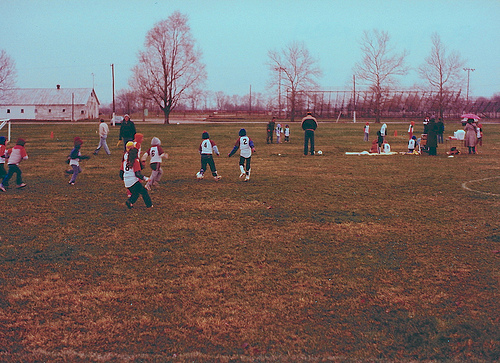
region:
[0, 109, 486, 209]
Children playing soccer on a field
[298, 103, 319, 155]
Man standing on a soccer field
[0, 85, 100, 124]
Large old white barn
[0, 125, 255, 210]
Children running after a soccer ball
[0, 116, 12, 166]
White frame soccer net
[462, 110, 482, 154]
Woman in a dress jacket and umbrella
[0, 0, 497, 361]
People on a soccer field on a cold day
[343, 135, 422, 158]
Children sitting on a blanket on the ground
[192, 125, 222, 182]
Small child kicking a soccer ball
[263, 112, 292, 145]
Man and two children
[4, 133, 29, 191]
child playing in field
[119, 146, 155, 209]
child playing in field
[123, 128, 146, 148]
child playing in field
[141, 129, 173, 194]
child playing in field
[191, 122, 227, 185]
child playing in field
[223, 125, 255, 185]
child playing in field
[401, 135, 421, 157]
child playing in field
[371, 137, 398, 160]
child playing in field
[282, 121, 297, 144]
child playing in field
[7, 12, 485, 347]
playing field with a game in progress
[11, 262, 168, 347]
brown grass on the field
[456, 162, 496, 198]
circular line drawn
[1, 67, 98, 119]
long building in the background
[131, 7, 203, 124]
bare tree on the side of the road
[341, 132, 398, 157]
people sitting on a white blanket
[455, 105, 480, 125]
two umbrellas opened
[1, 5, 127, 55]
clear and blue sky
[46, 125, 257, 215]
player's from both teams pursue the ball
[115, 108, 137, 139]
adult watching the action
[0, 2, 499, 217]
Children playing soccer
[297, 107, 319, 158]
The man is standing with his back to the camera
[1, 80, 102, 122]
A building behind the soccer field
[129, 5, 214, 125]
a tall tree with no leaves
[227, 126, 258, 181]
a girl with a 2 on her shirt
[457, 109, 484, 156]
the lady is holding a pink umbrella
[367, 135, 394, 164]
two kids sitting on a blanket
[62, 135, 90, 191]
the child is running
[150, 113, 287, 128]
a road beside the soccer field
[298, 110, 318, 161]
Man wearing a black jacket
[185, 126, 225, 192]
Child on the field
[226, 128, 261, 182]
Child wearing a jersey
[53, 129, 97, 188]
Child running on field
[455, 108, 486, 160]
Lady on a field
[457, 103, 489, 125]
Umbrella over ladies head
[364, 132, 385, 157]
Kid sitting on the field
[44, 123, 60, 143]
Safety cone on field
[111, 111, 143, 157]
Man wearing a black jacket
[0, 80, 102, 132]
Building in the background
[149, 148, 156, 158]
the number 6 on the shirt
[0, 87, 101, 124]
The old white barn in the baclground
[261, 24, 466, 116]
a trio of trees in the distance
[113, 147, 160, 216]
a young girl wearing black pants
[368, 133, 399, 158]
a pair of children sitting on a blanket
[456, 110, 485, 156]
a woman with a red umbrella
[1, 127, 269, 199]
a group of kids playing soccer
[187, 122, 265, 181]
a pair of kids wearing knit hats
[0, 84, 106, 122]
a two tone building in the distance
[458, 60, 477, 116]
a tall stadium lighting in the background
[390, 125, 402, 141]
a small orange cone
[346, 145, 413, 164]
a blanket laid out on a field